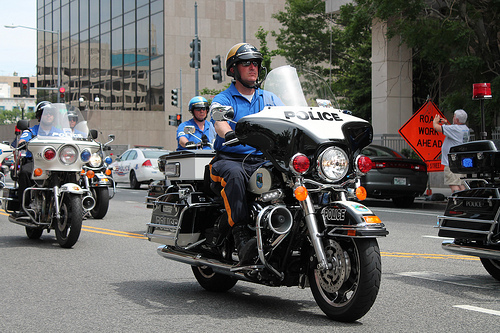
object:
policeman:
[174, 95, 215, 152]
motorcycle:
[141, 125, 219, 211]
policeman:
[15, 98, 64, 209]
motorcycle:
[1, 103, 102, 249]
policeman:
[207, 40, 290, 266]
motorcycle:
[144, 64, 390, 323]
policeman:
[65, 109, 100, 143]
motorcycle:
[70, 106, 119, 219]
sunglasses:
[233, 60, 261, 68]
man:
[431, 106, 472, 193]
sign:
[397, 95, 453, 173]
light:
[19, 76, 32, 98]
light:
[56, 84, 67, 104]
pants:
[206, 153, 263, 232]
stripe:
[208, 161, 236, 228]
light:
[42, 147, 57, 162]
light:
[79, 148, 93, 163]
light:
[469, 80, 495, 101]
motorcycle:
[434, 80, 500, 284]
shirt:
[210, 84, 288, 156]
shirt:
[16, 124, 66, 158]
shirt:
[174, 119, 216, 152]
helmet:
[188, 94, 210, 113]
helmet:
[224, 41, 264, 77]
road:
[2, 183, 500, 333]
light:
[286, 150, 311, 177]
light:
[352, 151, 374, 177]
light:
[170, 87, 180, 108]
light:
[208, 53, 225, 84]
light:
[188, 38, 204, 70]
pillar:
[369, 17, 414, 154]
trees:
[267, 0, 335, 128]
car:
[353, 144, 430, 209]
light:
[1, 21, 18, 32]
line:
[1, 207, 481, 265]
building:
[34, 0, 319, 149]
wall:
[33, 0, 167, 146]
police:
[283, 108, 344, 123]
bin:
[162, 148, 218, 182]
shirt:
[440, 123, 473, 165]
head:
[226, 42, 264, 90]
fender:
[320, 199, 390, 240]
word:
[321, 207, 347, 222]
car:
[110, 145, 176, 191]